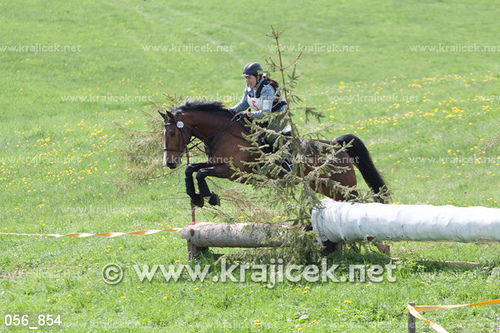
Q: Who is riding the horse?
A: A woman.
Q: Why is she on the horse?
A: A horse ride.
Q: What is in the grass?
A: Flowers.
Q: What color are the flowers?
A: Yellow.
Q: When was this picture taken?
A: Daytime.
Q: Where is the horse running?
A: In a field.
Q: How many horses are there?
A: 1.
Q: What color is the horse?
A: Brown.